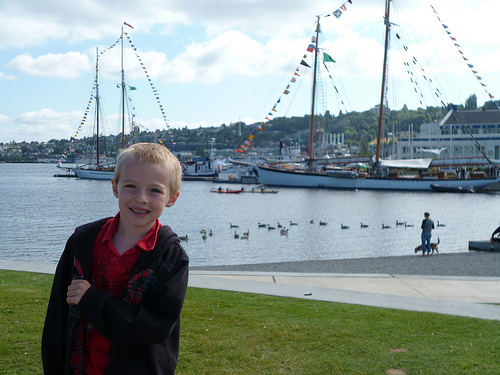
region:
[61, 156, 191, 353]
Boy wearing black sweatshirt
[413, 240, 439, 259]
Dog near water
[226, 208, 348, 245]
Water fowl floating in water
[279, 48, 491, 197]
Tall sailing ships docked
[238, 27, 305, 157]
Multi colored banners on sailing ships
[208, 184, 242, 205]
Red kayak in water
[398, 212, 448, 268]
Person standing next to dog on sandy shore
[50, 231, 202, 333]
Boy's left arm crossed over his chest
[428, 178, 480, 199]
Small boat next to large sailing ship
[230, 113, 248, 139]
Thin white tower on hill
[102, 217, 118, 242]
The left collar of the boy's shirt.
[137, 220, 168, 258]
The right collar of the boy's shirt.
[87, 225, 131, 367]
The red shirt the boy is wearing.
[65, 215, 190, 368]
The black sweater the boy is wearing.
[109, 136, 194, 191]
The blonde hair of the boy.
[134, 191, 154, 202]
The nose of the boy.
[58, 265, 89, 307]
The hand of the boy.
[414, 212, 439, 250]
The person standing near the water.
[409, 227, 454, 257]
The dog near the water.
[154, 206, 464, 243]
The ducks in the water.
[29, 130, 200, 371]
A young boy with blonde hair.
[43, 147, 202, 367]
A young boy wearing a red shirt.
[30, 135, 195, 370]
A young boy wearing a dark colored coat.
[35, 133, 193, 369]
A young boy wearing a long sleeve coat.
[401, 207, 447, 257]
A person looking out at the marina.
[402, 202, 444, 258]
A person and dog at the marina.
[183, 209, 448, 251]
Birds floating on the water.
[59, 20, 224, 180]
A sailing ship on the left.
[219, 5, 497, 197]
A sailing ship on the right.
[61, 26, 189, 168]
Flags on a sailing ship on the left.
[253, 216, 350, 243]
Ducks in the water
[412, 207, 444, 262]
A man and his dog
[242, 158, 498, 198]
Large longboat in the background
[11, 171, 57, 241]
Large body of water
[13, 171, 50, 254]
Ripples in the water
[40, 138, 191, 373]
Young boy posing for a picture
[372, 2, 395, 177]
Tall mast on a boat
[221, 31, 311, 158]
Decorative flags attached to a boat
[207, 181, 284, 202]
Canoes in the water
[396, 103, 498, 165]
Large building on the other side of the lake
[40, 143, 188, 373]
boy in red shirt in foreground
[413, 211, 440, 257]
person with dog standing at water's edge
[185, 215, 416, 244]
birds in the water in background between the boy and the person with a dog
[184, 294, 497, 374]
grass to the right of the boy in red shirt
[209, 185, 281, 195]
two small boats behind the birds in the water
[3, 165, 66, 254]
water to the left of the boy in red shirt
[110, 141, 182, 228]
face and head of the boy in the red shirt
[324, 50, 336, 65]
small green flag near top of boat to right of the boy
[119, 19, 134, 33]
top most flag on boat right behind the boy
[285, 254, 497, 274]
shore where the person with the dog is standing